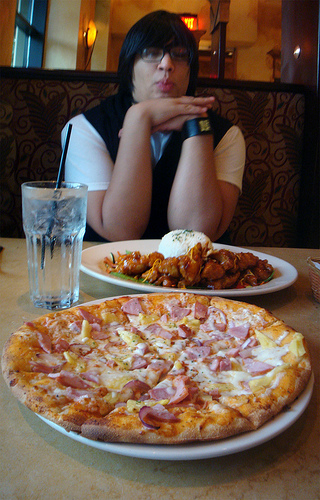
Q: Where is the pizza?
A: On the table.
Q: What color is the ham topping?
A: Pink.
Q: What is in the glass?
A: A drink.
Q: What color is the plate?
A: White.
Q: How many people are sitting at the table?
A: One.